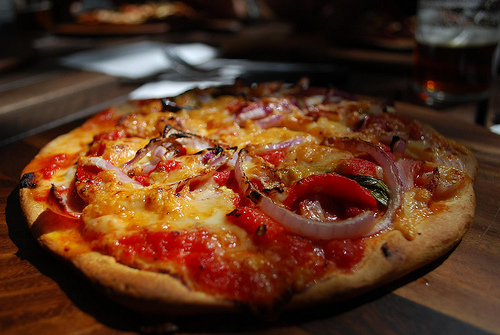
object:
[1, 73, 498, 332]
table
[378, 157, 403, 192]
wall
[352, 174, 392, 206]
leaf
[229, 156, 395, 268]
pepperoni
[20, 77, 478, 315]
pizza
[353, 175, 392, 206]
vegetable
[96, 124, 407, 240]
big onion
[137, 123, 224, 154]
burnt edge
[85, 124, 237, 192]
onion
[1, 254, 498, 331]
wood surface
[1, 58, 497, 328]
surface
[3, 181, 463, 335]
shadow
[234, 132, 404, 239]
onion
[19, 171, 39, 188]
spot